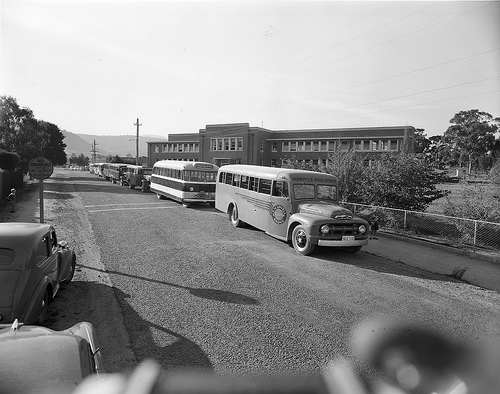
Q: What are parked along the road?
A: Buses.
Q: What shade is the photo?
A: Black and white.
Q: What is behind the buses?
A: A building.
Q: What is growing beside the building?
A: Grass and trees.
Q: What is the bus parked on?
A: A street.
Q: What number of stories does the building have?
A: Twp.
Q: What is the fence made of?
A: Metal.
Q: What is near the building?
A: A dirt road.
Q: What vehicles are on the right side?
A: Buses.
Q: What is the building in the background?
A: School.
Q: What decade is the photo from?
A: The 1950s.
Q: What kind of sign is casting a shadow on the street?
A: No parking sign.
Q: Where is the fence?
A: Beside the bus.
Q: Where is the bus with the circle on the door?
A: In the front.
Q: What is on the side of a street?
A: An old bus.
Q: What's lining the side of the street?
A: A line of buses.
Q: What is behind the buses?
A: A building.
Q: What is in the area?
A: Wires.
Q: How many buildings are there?
A: One.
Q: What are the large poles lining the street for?
A: Telephone wires.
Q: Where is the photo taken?
A: Street.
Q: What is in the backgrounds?
A: Mountains.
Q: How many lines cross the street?
A: Two.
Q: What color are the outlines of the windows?
A: White.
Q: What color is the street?
A: Gray.